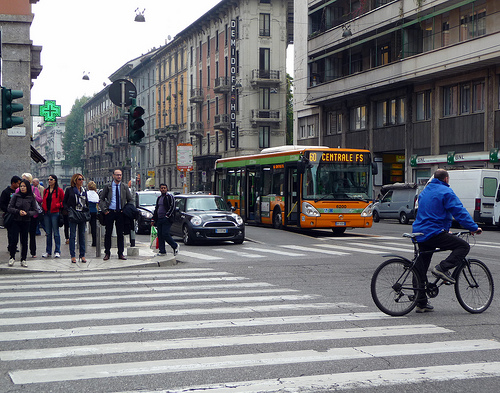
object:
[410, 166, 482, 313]
man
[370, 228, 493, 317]
bicycle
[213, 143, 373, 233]
bus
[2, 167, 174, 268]
people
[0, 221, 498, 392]
street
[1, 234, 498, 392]
lines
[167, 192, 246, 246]
car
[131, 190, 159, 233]
car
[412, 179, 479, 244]
jacket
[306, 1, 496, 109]
balcony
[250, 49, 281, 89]
balcony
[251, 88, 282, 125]
balcony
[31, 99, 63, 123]
sign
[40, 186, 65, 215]
jacket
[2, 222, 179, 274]
sidewalk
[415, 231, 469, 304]
pants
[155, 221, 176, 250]
pants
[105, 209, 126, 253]
pants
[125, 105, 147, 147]
traffic light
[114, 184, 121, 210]
tie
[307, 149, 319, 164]
number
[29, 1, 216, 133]
sky